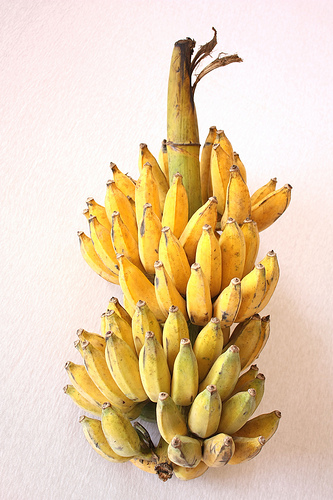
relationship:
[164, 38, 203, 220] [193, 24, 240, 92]
stem has a branch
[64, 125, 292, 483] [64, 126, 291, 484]
bananas are in a bushel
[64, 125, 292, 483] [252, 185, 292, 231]
bananas have a peel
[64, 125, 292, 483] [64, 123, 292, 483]
bananas are in a bunch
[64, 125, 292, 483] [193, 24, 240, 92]
bananas are on a branch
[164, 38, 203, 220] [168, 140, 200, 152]
stem have a ring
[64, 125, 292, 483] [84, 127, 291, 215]
bananas are pointed upward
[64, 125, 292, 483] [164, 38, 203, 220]
bananas have a stem